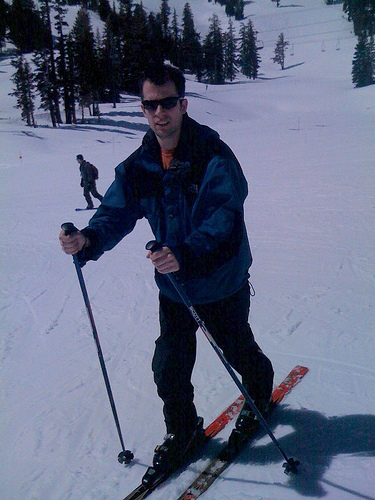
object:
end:
[117, 449, 134, 464]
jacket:
[75, 111, 253, 306]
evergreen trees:
[0, 0, 375, 128]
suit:
[69, 113, 254, 307]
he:
[58, 63, 274, 475]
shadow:
[169, 401, 375, 500]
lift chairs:
[288, 31, 340, 55]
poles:
[144, 240, 302, 477]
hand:
[145, 246, 180, 274]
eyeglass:
[141, 95, 185, 111]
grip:
[282, 456, 300, 475]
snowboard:
[74, 207, 98, 213]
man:
[76, 154, 105, 210]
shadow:
[28, 109, 149, 144]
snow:
[0, 0, 375, 500]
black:
[153, 454, 164, 469]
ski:
[172, 358, 309, 500]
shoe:
[152, 415, 204, 475]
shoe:
[227, 393, 273, 452]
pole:
[58, 221, 134, 466]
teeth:
[158, 120, 168, 124]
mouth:
[156, 118, 170, 126]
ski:
[122, 387, 246, 500]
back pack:
[79, 161, 99, 181]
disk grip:
[118, 449, 135, 464]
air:
[0, 91, 374, 138]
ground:
[0, 0, 375, 500]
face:
[142, 77, 182, 138]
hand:
[58, 229, 86, 256]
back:
[85, 162, 100, 184]